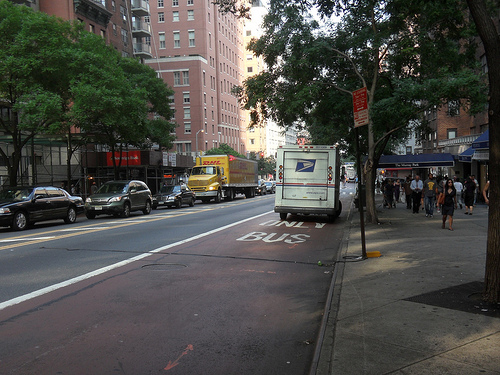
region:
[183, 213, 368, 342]
parking only for buses on the road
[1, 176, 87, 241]
a black car in the road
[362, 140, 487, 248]
people walking on the sidewalk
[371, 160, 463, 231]
people standing on the sidewalk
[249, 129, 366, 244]
a mail truck in the road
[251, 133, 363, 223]
a white mail truck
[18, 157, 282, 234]
cars parked in the road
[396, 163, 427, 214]
a man wearing a suite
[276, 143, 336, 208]
back of the white truck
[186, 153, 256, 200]
yellow truck driving down the street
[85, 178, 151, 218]
grey car driving down the street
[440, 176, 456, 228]
woman walking down the street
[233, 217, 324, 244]
white print on the street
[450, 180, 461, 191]
white top person is wearing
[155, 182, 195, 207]
dark colored car in front of the yellow truck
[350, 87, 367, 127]
red and white sign on the sidewalk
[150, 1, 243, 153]
tall brick building in the background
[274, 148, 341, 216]
back of white truck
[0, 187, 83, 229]
car driving in road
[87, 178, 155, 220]
car driving in road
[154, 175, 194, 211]
car driving in road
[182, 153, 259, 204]
yellow truck driving in road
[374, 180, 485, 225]
crowd of people walking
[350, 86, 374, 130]
red and white sign in street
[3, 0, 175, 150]
green trees over street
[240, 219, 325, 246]
white writing in street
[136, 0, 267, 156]
building behind yellow bus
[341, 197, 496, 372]
part of a sidewalk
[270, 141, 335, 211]
the back of a postal truck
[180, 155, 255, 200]
a large yellow and red truck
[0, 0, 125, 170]
a large green tree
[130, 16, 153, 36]
a balcony of a building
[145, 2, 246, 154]
a large brown building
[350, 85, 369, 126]
a red and white street sign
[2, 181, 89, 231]
a black car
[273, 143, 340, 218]
a US Mail truck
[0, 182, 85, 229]
a black car on road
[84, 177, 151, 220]
a silver car on road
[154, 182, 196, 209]
a black car on road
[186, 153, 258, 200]
a yellow commercial truck on road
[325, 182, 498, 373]
a paved city sidewalk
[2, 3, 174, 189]
large green tree in distance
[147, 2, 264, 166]
large building in distance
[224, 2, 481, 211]
large green tree in distance